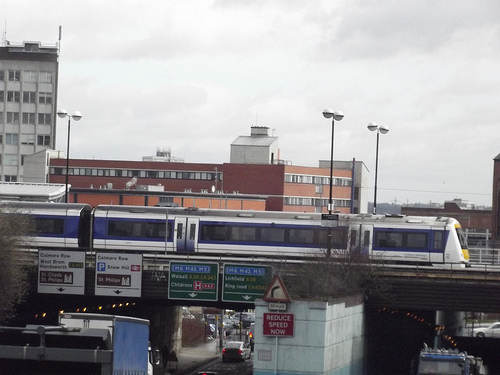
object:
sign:
[263, 312, 295, 337]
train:
[0, 198, 470, 267]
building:
[220, 126, 353, 212]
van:
[57, 312, 162, 374]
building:
[1, 42, 58, 197]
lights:
[332, 111, 345, 121]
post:
[328, 119, 334, 212]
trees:
[292, 211, 378, 304]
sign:
[167, 260, 219, 301]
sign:
[95, 253, 144, 298]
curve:
[267, 283, 282, 299]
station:
[1, 182, 72, 200]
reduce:
[266, 312, 292, 322]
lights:
[96, 306, 104, 309]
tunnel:
[0, 291, 144, 375]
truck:
[414, 341, 465, 374]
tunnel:
[361, 311, 499, 374]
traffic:
[0, 310, 154, 374]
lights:
[221, 348, 226, 352]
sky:
[0, 0, 499, 212]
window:
[256, 226, 286, 244]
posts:
[372, 132, 380, 213]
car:
[222, 339, 252, 361]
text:
[268, 321, 273, 327]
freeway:
[177, 311, 253, 374]